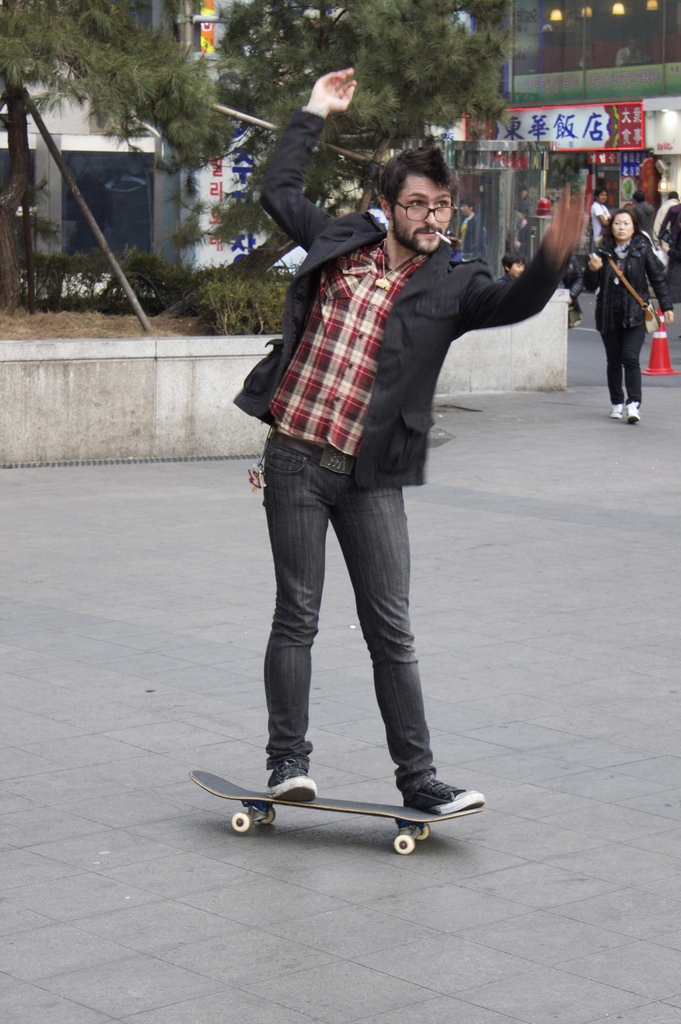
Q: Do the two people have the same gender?
A: No, they are both male and female.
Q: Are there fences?
A: No, there are no fences.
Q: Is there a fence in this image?
A: No, there are no fences.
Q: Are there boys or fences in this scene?
A: No, there are no fences or boys.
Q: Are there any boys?
A: No, there are no boys.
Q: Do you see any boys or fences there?
A: No, there are no boys or fences.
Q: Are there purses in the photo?
A: Yes, there is a purse.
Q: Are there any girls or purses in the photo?
A: Yes, there is a purse.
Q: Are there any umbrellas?
A: No, there are no umbrellas.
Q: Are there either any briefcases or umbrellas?
A: No, there are no umbrellas or briefcases.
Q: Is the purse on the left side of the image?
A: No, the purse is on the right of the image.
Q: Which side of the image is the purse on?
A: The purse is on the right of the image.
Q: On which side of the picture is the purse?
A: The purse is on the right of the image.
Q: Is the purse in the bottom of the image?
A: No, the purse is in the top of the image.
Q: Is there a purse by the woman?
A: Yes, there is a purse by the woman.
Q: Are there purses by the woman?
A: Yes, there is a purse by the woman.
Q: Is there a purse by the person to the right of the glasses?
A: Yes, there is a purse by the woman.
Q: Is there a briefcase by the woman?
A: No, there is a purse by the woman.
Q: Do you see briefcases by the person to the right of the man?
A: No, there is a purse by the woman.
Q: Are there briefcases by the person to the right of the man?
A: No, there is a purse by the woman.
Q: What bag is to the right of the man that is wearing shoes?
A: The bag is a purse.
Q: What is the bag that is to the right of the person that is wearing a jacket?
A: The bag is a purse.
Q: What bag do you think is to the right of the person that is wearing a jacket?
A: The bag is a purse.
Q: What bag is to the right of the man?
A: The bag is a purse.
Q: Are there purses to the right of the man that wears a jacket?
A: Yes, there is a purse to the right of the man.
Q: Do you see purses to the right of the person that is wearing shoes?
A: Yes, there is a purse to the right of the man.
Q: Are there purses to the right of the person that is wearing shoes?
A: Yes, there is a purse to the right of the man.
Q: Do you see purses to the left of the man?
A: No, the purse is to the right of the man.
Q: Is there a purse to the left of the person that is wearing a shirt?
A: No, the purse is to the right of the man.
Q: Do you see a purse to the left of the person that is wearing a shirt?
A: No, the purse is to the right of the man.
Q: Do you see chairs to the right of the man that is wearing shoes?
A: No, there is a purse to the right of the man.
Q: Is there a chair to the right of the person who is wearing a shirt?
A: No, there is a purse to the right of the man.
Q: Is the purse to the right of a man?
A: Yes, the purse is to the right of a man.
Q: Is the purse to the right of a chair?
A: No, the purse is to the right of a man.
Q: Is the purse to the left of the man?
A: No, the purse is to the right of the man.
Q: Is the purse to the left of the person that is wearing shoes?
A: No, the purse is to the right of the man.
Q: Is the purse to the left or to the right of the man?
A: The purse is to the right of the man.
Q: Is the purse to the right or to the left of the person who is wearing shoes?
A: The purse is to the right of the man.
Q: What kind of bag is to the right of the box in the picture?
A: The bag is a purse.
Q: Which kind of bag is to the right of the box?
A: The bag is a purse.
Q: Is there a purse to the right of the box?
A: Yes, there is a purse to the right of the box.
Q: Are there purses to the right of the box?
A: Yes, there is a purse to the right of the box.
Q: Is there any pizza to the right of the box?
A: No, there is a purse to the right of the box.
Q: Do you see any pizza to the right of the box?
A: No, there is a purse to the right of the box.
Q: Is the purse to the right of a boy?
A: No, the purse is to the right of the box.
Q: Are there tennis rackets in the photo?
A: No, there are no tennis rackets.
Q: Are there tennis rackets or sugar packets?
A: No, there are no tennis rackets or sugar packets.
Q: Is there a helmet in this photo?
A: No, there are no helmets.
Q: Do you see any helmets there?
A: No, there are no helmets.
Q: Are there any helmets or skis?
A: No, there are no helmets or skis.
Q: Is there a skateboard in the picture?
A: Yes, there is a skateboard.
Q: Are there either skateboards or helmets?
A: Yes, there is a skateboard.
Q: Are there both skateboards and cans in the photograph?
A: No, there is a skateboard but no cans.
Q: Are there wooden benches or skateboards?
A: Yes, there is a wood skateboard.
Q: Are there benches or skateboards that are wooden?
A: Yes, the skateboard is wooden.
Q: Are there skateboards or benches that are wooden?
A: Yes, the skateboard is wooden.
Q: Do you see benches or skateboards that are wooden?
A: Yes, the skateboard is wooden.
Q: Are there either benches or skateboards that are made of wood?
A: Yes, the skateboard is made of wood.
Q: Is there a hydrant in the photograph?
A: No, there are no fire hydrants.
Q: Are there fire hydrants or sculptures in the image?
A: No, there are no fire hydrants or sculptures.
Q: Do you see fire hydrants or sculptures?
A: No, there are no fire hydrants or sculptures.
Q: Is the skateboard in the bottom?
A: Yes, the skateboard is in the bottom of the image.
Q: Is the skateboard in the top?
A: No, the skateboard is in the bottom of the image.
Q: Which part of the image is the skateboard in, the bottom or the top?
A: The skateboard is in the bottom of the image.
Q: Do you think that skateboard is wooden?
A: Yes, the skateboard is wooden.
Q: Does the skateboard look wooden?
A: Yes, the skateboard is wooden.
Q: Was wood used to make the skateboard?
A: Yes, the skateboard is made of wood.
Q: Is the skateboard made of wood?
A: Yes, the skateboard is made of wood.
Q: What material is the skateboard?
A: The skateboard is made of wood.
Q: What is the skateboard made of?
A: The skateboard is made of wood.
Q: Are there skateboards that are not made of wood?
A: No, there is a skateboard but it is made of wood.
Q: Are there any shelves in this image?
A: No, there are no shelves.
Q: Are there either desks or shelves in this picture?
A: No, there are no shelves or desks.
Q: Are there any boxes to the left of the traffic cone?
A: Yes, there is a box to the left of the traffic cone.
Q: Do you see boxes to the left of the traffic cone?
A: Yes, there is a box to the left of the traffic cone.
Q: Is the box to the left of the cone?
A: Yes, the box is to the left of the cone.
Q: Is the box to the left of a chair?
A: No, the box is to the left of the cone.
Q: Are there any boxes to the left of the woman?
A: Yes, there is a box to the left of the woman.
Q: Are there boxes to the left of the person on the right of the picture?
A: Yes, there is a box to the left of the woman.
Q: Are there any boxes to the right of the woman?
A: No, the box is to the left of the woman.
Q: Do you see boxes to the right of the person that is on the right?
A: No, the box is to the left of the woman.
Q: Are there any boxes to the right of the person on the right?
A: No, the box is to the left of the woman.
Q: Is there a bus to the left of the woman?
A: No, there is a box to the left of the woman.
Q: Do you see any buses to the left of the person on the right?
A: No, there is a box to the left of the woman.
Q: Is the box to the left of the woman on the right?
A: Yes, the box is to the left of the woman.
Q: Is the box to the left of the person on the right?
A: Yes, the box is to the left of the woman.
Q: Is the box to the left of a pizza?
A: No, the box is to the left of the woman.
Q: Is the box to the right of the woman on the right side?
A: No, the box is to the left of the woman.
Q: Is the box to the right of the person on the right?
A: No, the box is to the left of the woman.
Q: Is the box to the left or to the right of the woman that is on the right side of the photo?
A: The box is to the left of the woman.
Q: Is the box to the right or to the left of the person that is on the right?
A: The box is to the left of the woman.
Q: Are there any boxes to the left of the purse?
A: Yes, there is a box to the left of the purse.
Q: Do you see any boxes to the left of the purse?
A: Yes, there is a box to the left of the purse.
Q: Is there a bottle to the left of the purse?
A: No, there is a box to the left of the purse.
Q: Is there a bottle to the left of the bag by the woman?
A: No, there is a box to the left of the purse.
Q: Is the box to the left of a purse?
A: Yes, the box is to the left of a purse.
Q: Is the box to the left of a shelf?
A: No, the box is to the left of a purse.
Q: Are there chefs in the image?
A: No, there are no chefs.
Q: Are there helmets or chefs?
A: No, there are no chefs or helmets.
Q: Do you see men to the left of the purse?
A: Yes, there is a man to the left of the purse.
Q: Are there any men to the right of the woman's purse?
A: No, the man is to the left of the purse.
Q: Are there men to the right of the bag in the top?
A: No, the man is to the left of the purse.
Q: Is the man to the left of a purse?
A: Yes, the man is to the left of a purse.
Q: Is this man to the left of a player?
A: No, the man is to the left of a purse.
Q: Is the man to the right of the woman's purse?
A: No, the man is to the left of the purse.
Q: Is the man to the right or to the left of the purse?
A: The man is to the left of the purse.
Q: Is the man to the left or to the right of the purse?
A: The man is to the left of the purse.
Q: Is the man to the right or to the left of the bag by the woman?
A: The man is to the left of the purse.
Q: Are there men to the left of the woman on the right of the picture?
A: Yes, there is a man to the left of the woman.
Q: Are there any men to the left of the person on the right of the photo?
A: Yes, there is a man to the left of the woman.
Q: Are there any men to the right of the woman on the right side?
A: No, the man is to the left of the woman.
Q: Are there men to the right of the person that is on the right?
A: No, the man is to the left of the woman.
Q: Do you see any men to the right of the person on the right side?
A: No, the man is to the left of the woman.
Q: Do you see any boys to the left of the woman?
A: No, there is a man to the left of the woman.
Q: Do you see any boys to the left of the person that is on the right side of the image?
A: No, there is a man to the left of the woman.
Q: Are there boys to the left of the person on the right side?
A: No, there is a man to the left of the woman.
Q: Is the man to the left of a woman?
A: Yes, the man is to the left of a woman.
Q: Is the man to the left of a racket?
A: No, the man is to the left of a woman.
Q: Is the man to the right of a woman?
A: No, the man is to the left of a woman.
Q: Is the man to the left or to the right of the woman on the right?
A: The man is to the left of the woman.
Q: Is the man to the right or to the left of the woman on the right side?
A: The man is to the left of the woman.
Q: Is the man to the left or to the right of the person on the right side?
A: The man is to the left of the woman.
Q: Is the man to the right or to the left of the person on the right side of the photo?
A: The man is to the left of the woman.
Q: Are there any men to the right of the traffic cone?
A: No, the man is to the left of the traffic cone.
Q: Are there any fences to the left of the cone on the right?
A: No, there is a man to the left of the traffic cone.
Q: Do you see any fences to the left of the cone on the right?
A: No, there is a man to the left of the traffic cone.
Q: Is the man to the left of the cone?
A: Yes, the man is to the left of the cone.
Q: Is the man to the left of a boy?
A: No, the man is to the left of the cone.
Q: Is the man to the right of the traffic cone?
A: No, the man is to the left of the traffic cone.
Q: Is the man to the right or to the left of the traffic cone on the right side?
A: The man is to the left of the cone.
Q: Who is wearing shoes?
A: The man is wearing shoes.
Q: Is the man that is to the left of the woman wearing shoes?
A: Yes, the man is wearing shoes.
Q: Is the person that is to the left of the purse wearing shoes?
A: Yes, the man is wearing shoes.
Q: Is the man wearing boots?
A: No, the man is wearing shoes.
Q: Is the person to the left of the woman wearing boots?
A: No, the man is wearing shoes.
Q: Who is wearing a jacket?
A: The man is wearing a jacket.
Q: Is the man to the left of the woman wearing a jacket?
A: Yes, the man is wearing a jacket.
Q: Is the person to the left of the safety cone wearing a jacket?
A: Yes, the man is wearing a jacket.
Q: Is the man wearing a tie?
A: No, the man is wearing a jacket.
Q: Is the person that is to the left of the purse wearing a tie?
A: No, the man is wearing a jacket.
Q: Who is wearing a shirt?
A: The man is wearing a shirt.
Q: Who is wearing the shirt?
A: The man is wearing a shirt.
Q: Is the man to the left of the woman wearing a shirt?
A: Yes, the man is wearing a shirt.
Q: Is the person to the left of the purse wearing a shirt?
A: Yes, the man is wearing a shirt.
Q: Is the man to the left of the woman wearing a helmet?
A: No, the man is wearing a shirt.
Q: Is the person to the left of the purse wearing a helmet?
A: No, the man is wearing a shirt.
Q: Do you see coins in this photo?
A: No, there are no coins.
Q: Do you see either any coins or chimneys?
A: No, there are no coins or chimneys.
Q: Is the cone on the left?
A: No, the cone is on the right of the image.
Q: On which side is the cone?
A: The cone is on the right of the image.